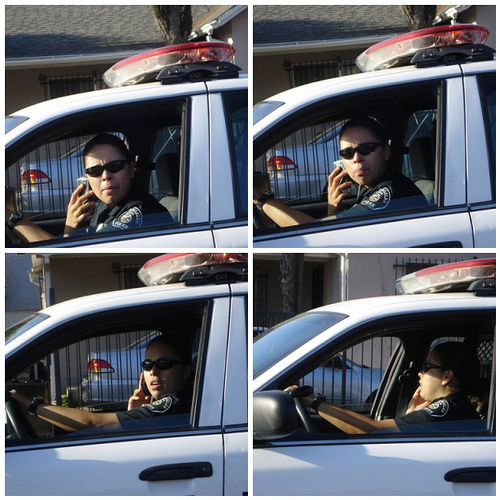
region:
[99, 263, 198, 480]
cop in a car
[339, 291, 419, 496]
cop in a car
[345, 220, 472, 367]
cop in a car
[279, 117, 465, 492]
cop in a car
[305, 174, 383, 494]
cop in a car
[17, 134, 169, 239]
a police officer on phone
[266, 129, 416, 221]
a police officer on phone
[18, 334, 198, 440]
a police officer on phone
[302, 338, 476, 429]
a police officer on phone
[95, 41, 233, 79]
red and white emergency lights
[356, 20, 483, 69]
red and white emergency lights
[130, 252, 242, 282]
red and white emergency lights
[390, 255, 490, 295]
red and white emergency lights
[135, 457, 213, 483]
a black door handle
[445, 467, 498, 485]
a black door handle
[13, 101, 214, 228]
side window of car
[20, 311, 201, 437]
side window of car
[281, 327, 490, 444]
side window of car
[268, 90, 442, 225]
side window of car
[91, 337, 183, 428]
police officer inside of car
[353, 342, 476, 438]
police officer inside of car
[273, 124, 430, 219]
police officer inside of car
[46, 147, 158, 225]
police officer inside of car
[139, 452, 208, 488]
black handle of car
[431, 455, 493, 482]
black handle of car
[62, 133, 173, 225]
the man in the car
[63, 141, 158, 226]
the man driving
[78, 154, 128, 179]
the black sunglasses on the man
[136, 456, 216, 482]
the handle on the door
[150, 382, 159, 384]
the man's teeth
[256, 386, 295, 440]
the mirror on the driver's side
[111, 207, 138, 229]
the patch on the uniform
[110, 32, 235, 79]
the light on top of the car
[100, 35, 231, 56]
the red light on the car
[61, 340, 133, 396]
the black gate in the bak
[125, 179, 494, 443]
a car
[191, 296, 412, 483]
a car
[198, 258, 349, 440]
a car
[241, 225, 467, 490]
a car